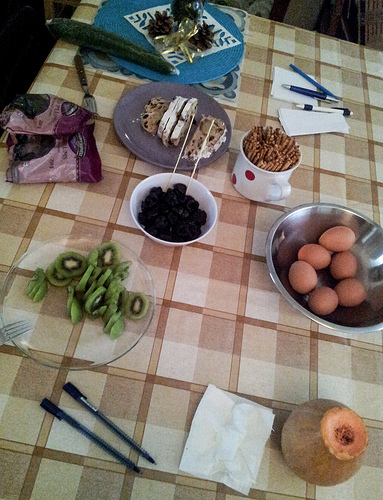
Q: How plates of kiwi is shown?
A: One.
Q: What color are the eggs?
A: Brown.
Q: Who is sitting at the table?
A: No one.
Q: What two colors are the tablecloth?
A: Brown and white.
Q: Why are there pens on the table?
A: To write with.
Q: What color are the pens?
A: Black.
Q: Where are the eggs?
A: In a bowl.